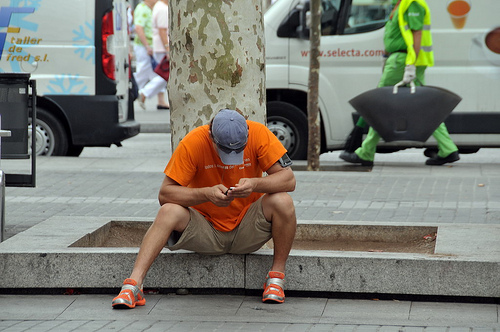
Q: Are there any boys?
A: No, there are no boys.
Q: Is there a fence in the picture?
A: No, there are no fences.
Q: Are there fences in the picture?
A: No, there are no fences.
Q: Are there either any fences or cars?
A: No, there are no fences or cars.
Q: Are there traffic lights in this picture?
A: No, there are no traffic lights.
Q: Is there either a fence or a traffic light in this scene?
A: No, there are no traffic lights or fences.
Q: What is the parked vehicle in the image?
A: The vehicle is a van.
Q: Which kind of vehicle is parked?
A: The vehicle is a van.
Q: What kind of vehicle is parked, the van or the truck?
A: The van is parked.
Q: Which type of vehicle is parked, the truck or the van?
A: The van is parked.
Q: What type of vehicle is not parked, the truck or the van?
A: The truck is not parked.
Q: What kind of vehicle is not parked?
A: The vehicle is a truck.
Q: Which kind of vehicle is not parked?
A: The vehicle is a truck.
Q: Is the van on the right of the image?
A: Yes, the van is on the right of the image.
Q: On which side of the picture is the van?
A: The van is on the right of the image.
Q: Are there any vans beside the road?
A: Yes, there is a van beside the road.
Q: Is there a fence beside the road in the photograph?
A: No, there is a van beside the road.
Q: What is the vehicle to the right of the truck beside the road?
A: The vehicle is a van.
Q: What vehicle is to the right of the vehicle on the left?
A: The vehicle is a van.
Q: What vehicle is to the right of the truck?
A: The vehicle is a van.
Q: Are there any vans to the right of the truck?
A: Yes, there is a van to the right of the truck.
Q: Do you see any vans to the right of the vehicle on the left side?
A: Yes, there is a van to the right of the truck.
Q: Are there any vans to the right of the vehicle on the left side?
A: Yes, there is a van to the right of the truck.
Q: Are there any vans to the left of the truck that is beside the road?
A: No, the van is to the right of the truck.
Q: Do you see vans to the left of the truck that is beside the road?
A: No, the van is to the right of the truck.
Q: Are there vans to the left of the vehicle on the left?
A: No, the van is to the right of the truck.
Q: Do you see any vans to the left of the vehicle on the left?
A: No, the van is to the right of the truck.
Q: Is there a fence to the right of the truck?
A: No, there is a van to the right of the truck.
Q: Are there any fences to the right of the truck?
A: No, there is a van to the right of the truck.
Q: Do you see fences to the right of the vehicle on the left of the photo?
A: No, there is a van to the right of the truck.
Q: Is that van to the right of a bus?
A: No, the van is to the right of the truck.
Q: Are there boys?
A: No, there are no boys.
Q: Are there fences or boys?
A: No, there are no boys or fences.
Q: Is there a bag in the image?
A: Yes, there is a bag.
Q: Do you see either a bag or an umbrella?
A: Yes, there is a bag.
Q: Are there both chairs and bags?
A: No, there is a bag but no chairs.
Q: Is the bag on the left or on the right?
A: The bag is on the right of the image.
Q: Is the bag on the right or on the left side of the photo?
A: The bag is on the right of the image.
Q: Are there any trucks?
A: Yes, there is a truck.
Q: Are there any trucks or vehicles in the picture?
A: Yes, there is a truck.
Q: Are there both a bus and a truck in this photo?
A: No, there is a truck but no buses.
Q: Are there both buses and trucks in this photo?
A: No, there is a truck but no buses.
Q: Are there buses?
A: No, there are no buses.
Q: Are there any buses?
A: No, there are no buses.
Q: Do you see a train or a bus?
A: No, there are no buses or trains.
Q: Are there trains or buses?
A: No, there are no buses or trains.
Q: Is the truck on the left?
A: Yes, the truck is on the left of the image.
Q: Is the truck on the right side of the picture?
A: No, the truck is on the left of the image.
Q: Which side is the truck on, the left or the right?
A: The truck is on the left of the image.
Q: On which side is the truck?
A: The truck is on the left of the image.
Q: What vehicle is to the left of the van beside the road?
A: The vehicle is a truck.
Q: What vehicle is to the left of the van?
A: The vehicle is a truck.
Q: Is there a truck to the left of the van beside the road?
A: Yes, there is a truck to the left of the van.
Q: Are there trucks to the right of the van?
A: No, the truck is to the left of the van.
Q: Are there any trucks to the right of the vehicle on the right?
A: No, the truck is to the left of the van.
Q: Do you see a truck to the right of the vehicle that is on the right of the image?
A: No, the truck is to the left of the van.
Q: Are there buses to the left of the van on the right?
A: No, there is a truck to the left of the van.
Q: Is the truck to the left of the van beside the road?
A: Yes, the truck is to the left of the van.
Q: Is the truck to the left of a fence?
A: No, the truck is to the left of the van.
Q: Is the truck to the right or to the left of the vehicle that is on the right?
A: The truck is to the left of the van.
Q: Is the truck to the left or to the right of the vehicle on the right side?
A: The truck is to the left of the van.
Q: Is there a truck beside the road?
A: Yes, there is a truck beside the road.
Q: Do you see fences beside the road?
A: No, there is a truck beside the road.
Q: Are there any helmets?
A: No, there are no helmets.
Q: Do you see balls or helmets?
A: No, there are no helmets or balls.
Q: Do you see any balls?
A: No, there are no balls.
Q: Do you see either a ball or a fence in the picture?
A: No, there are no balls or fences.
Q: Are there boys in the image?
A: No, there are no boys.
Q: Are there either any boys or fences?
A: No, there are no boys or fences.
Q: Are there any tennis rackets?
A: No, there are no tennis rackets.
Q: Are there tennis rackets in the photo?
A: No, there are no tennis rackets.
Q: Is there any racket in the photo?
A: No, there are no rackets.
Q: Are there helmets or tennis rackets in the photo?
A: No, there are no tennis rackets or helmets.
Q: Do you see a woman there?
A: No, there are no women.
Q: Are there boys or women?
A: No, there are no women or boys.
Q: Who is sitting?
A: The man is sitting.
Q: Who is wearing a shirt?
A: The man is wearing a shirt.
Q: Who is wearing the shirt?
A: The man is wearing a shirt.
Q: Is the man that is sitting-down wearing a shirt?
A: Yes, the man is wearing a shirt.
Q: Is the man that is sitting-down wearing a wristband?
A: No, the man is wearing a shirt.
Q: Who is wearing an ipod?
A: The man is wearing an ipod.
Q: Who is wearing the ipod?
A: The man is wearing an ipod.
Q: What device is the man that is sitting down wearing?
A: The man is wearing an ipod.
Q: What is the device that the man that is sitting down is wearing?
A: The device is an ipod.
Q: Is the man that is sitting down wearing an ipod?
A: Yes, the man is wearing an ipod.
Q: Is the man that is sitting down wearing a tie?
A: No, the man is wearing an ipod.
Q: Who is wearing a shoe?
A: The man is wearing a shoe.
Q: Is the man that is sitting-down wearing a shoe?
A: Yes, the man is wearing a shoe.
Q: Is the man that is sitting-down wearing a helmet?
A: No, the man is wearing a shoe.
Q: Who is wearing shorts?
A: The man is wearing shorts.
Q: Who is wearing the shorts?
A: The man is wearing shorts.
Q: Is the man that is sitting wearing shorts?
A: Yes, the man is wearing shorts.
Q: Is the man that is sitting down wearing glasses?
A: No, the man is wearing shorts.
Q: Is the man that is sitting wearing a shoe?
A: Yes, the man is wearing a shoe.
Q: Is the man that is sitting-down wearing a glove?
A: No, the man is wearing a shoe.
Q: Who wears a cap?
A: The man wears a cap.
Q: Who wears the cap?
A: The man wears a cap.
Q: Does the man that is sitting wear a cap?
A: Yes, the man wears a cap.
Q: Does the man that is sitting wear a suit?
A: No, the man wears a cap.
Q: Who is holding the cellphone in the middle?
A: The man is holding the cell phone.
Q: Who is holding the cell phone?
A: The man is holding the cell phone.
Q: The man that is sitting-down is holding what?
A: The man is holding the mobile phone.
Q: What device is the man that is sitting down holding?
A: The man is holding the cell phone.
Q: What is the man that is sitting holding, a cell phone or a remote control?
A: The man is holding a cell phone.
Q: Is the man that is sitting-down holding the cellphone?
A: Yes, the man is holding the cellphone.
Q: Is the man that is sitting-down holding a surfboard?
A: No, the man is holding the cellphone.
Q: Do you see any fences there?
A: No, there are no fences.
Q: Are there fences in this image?
A: No, there are no fences.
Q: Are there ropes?
A: No, there are no ropes.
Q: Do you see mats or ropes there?
A: No, there are no ropes or mats.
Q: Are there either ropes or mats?
A: No, there are no ropes or mats.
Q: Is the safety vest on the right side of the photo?
A: Yes, the safety vest is on the right of the image.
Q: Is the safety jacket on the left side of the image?
A: No, the safety jacket is on the right of the image.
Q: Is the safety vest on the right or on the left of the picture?
A: The safety vest is on the right of the image.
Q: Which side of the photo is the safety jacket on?
A: The safety jacket is on the right of the image.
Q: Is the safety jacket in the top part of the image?
A: Yes, the safety jacket is in the top of the image.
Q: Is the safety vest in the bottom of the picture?
A: No, the safety vest is in the top of the image.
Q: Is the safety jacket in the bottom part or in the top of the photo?
A: The safety jacket is in the top of the image.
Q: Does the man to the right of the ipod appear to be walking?
A: Yes, the man is walking.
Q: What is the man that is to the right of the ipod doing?
A: The man is walking.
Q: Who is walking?
A: The man is walking.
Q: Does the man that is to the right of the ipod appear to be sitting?
A: No, the man is walking.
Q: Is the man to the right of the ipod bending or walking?
A: The man is walking.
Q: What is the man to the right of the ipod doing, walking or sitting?
A: The man is walking.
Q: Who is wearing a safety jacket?
A: The man is wearing a safety jacket.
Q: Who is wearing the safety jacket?
A: The man is wearing a safety jacket.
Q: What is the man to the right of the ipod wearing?
A: The man is wearing a safety vest.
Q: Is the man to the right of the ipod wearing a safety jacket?
A: Yes, the man is wearing a safety jacket.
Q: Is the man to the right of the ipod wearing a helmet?
A: No, the man is wearing a safety jacket.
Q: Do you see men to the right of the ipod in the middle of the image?
A: Yes, there is a man to the right of the ipod.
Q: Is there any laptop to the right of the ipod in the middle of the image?
A: No, there is a man to the right of the ipod.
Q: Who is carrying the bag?
A: The man is carrying the bag.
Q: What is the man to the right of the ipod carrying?
A: The man is carrying a bag.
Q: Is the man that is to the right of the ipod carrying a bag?
A: Yes, the man is carrying a bag.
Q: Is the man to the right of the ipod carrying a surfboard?
A: No, the man is carrying a bag.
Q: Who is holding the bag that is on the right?
A: The man is holding the bag.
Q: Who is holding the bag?
A: The man is holding the bag.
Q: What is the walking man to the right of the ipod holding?
A: The man is holding the bag.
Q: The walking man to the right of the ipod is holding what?
A: The man is holding the bag.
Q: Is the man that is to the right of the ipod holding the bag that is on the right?
A: Yes, the man is holding the bag.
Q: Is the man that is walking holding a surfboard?
A: No, the man is holding the bag.